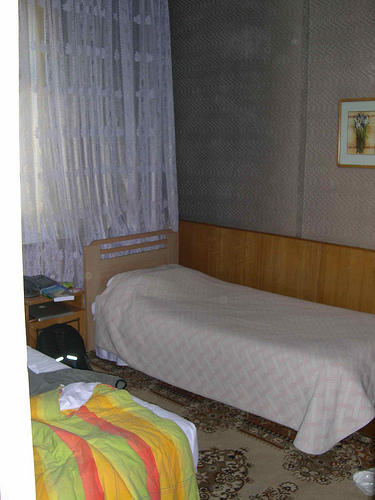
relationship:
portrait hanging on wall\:
[333, 96, 370, 173] [152, 0, 373, 312]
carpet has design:
[79, 354, 371, 499] [195, 445, 254, 497]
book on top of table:
[42, 282, 76, 303] [22, 288, 91, 360]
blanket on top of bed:
[29, 365, 130, 397] [26, 338, 199, 499]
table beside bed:
[22, 288, 91, 360] [81, 225, 374, 450]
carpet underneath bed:
[79, 354, 371, 499] [81, 225, 374, 450]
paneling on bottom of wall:
[175, 217, 372, 316] [152, 0, 373, 312]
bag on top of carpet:
[33, 323, 93, 371] [79, 354, 371, 499]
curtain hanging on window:
[21, 2, 181, 291] [29, 2, 149, 227]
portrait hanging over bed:
[333, 96, 370, 173] [81, 225, 374, 450]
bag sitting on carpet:
[33, 323, 93, 371] [79, 354, 371, 499]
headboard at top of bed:
[80, 228, 181, 357] [81, 225, 374, 450]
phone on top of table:
[23, 276, 60, 295] [22, 288, 91, 360]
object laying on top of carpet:
[350, 469, 374, 499] [79, 354, 371, 499]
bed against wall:
[81, 225, 374, 450] [152, 0, 373, 312]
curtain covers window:
[21, 2, 181, 291] [29, 2, 149, 227]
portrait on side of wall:
[333, 96, 370, 173] [152, 0, 373, 312]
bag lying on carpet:
[33, 323, 93, 371] [79, 354, 371, 499]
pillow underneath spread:
[107, 264, 204, 297] [94, 265, 373, 454]